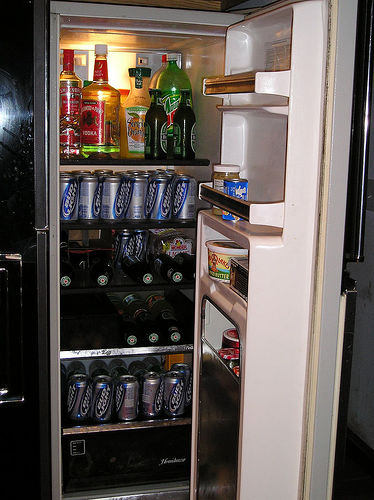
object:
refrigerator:
[34, 3, 372, 497]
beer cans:
[61, 165, 79, 221]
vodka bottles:
[82, 44, 122, 157]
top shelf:
[60, 28, 220, 175]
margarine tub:
[206, 237, 248, 290]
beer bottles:
[55, 238, 73, 286]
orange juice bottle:
[119, 65, 156, 160]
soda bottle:
[147, 50, 195, 165]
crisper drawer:
[64, 431, 198, 491]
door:
[185, 2, 372, 492]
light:
[84, 49, 139, 91]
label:
[121, 105, 148, 156]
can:
[127, 171, 151, 219]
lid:
[218, 343, 246, 363]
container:
[224, 174, 249, 226]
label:
[62, 77, 81, 159]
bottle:
[171, 88, 199, 162]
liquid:
[121, 82, 150, 159]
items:
[57, 47, 84, 158]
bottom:
[43, 428, 192, 495]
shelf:
[64, 161, 212, 239]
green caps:
[58, 273, 75, 290]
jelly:
[220, 346, 238, 364]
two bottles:
[141, 89, 199, 163]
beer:
[143, 86, 169, 158]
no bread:
[63, 48, 249, 457]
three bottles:
[105, 294, 181, 343]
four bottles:
[61, 244, 81, 289]